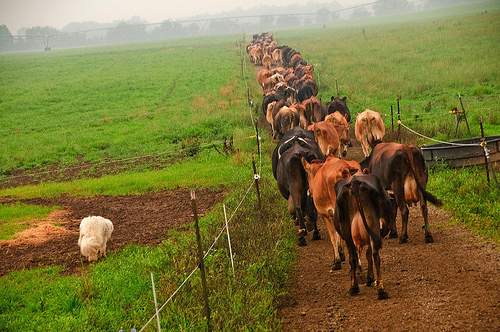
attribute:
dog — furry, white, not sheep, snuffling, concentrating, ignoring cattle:
[70, 211, 117, 267]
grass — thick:
[84, 257, 116, 283]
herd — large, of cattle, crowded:
[242, 25, 450, 304]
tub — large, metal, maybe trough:
[420, 130, 499, 177]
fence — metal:
[109, 32, 261, 332]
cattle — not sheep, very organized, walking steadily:
[242, 30, 448, 317]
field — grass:
[1, 33, 268, 332]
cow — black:
[262, 91, 280, 117]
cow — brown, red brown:
[296, 150, 367, 273]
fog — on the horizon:
[0, 0, 499, 54]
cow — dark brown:
[327, 167, 397, 306]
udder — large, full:
[348, 204, 373, 258]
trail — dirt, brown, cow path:
[244, 31, 499, 330]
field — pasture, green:
[2, 9, 499, 331]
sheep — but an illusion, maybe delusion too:
[253, 175, 260, 180]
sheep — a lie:
[252, 174, 258, 182]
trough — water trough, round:
[410, 131, 499, 172]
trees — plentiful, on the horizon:
[1, 0, 499, 56]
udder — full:
[395, 168, 424, 210]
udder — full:
[283, 192, 307, 228]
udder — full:
[365, 131, 378, 146]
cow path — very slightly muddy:
[277, 183, 499, 332]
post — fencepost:
[187, 187, 222, 332]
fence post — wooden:
[188, 188, 220, 330]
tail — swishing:
[328, 115, 355, 130]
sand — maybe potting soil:
[1, 204, 82, 258]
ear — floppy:
[87, 237, 102, 252]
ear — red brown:
[298, 157, 314, 173]